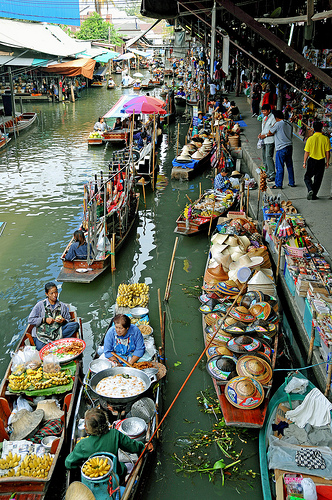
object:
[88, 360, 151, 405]
bowl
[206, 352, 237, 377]
blue decal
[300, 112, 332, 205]
man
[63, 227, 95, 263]
woman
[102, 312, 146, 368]
woman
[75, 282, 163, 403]
boat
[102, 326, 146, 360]
shirt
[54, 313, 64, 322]
food.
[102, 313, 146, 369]
hoodie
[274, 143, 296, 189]
blue jeans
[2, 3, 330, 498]
canal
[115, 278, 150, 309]
bananas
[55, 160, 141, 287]
boat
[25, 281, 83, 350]
woman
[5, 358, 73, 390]
bananas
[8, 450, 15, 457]
banana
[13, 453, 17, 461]
banana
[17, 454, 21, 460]
banana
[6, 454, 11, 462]
banana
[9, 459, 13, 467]
banana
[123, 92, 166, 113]
umbrellas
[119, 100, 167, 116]
umbrellas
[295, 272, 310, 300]
books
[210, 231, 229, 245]
hats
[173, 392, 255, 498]
vegetation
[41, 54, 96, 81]
covering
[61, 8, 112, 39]
building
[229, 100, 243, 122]
people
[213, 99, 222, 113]
people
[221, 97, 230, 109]
people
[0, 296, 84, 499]
boat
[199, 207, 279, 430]
boat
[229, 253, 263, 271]
hat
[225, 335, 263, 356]
hat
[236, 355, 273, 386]
hat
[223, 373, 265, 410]
hat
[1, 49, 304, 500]
water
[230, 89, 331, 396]
pier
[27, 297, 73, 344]
shirt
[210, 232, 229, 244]
hat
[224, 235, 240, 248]
hat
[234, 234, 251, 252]
hat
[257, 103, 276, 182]
man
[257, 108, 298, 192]
man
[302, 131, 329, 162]
shirt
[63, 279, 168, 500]
boat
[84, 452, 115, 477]
bananas